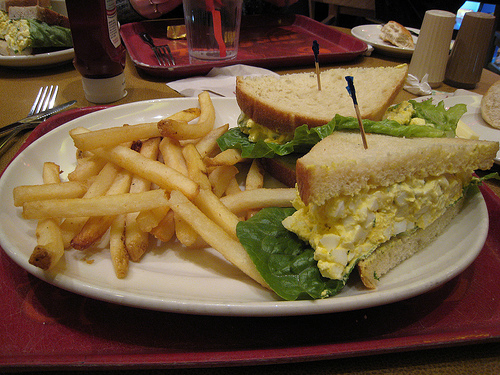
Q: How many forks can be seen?
A: Two.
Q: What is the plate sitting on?
A: Tray.